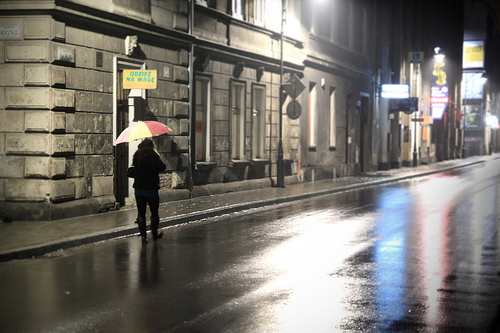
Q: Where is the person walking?
A: On a street.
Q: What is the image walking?
A: A person.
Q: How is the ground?
A: Wet.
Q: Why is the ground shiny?
A: There is light reflecting on the wet ground.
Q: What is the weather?
A: Rainy.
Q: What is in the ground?
A: Concrete.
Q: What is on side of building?
A: Windows.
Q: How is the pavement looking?
A: Wet.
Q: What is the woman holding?
A: Umbrella.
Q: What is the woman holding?
A: Umbrella.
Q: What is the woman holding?
A: Umbrella.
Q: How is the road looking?
A: Watery.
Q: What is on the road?
A: Right reflection.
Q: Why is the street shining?
A: It's wet.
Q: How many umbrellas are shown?
A: One.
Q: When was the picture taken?
A: Night.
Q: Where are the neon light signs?
A: Upper right.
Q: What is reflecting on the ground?
A: Lights.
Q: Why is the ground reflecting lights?
A: It's wet.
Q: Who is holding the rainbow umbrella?
A: The woman.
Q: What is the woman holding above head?
A: An umbrella.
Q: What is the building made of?
A: Cinder block.